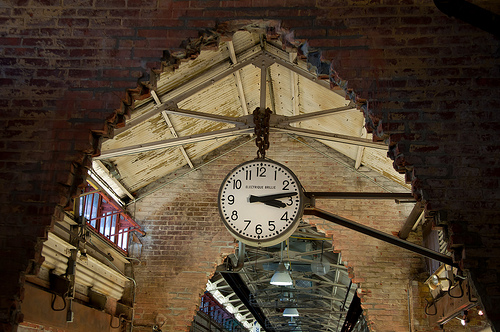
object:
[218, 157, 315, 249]
clock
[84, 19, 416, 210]
ceiling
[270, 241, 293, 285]
ceiling light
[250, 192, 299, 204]
hand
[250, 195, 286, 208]
hand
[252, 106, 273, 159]
chain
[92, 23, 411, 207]
beam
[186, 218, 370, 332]
ceiling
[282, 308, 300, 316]
ceiling light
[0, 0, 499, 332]
wall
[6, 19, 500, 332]
entrance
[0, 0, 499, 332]
building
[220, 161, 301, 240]
face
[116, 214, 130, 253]
window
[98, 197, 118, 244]
window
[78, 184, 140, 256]
window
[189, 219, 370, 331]
opening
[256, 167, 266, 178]
number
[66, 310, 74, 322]
electrical box